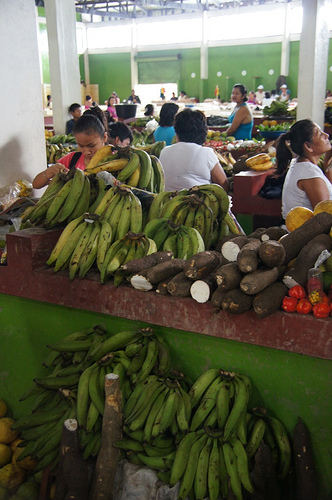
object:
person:
[219, 79, 255, 140]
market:
[0, 4, 332, 500]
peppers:
[279, 292, 300, 318]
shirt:
[276, 156, 332, 228]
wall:
[46, 35, 331, 108]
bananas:
[67, 215, 95, 283]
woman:
[30, 103, 129, 203]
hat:
[257, 83, 265, 91]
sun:
[40, 1, 332, 51]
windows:
[200, 0, 291, 51]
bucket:
[113, 102, 139, 123]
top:
[228, 102, 253, 138]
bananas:
[52, 162, 86, 227]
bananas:
[177, 220, 207, 261]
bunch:
[24, 162, 94, 223]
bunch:
[84, 139, 167, 196]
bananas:
[220, 367, 252, 445]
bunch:
[141, 215, 208, 262]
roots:
[218, 238, 242, 263]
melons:
[0, 411, 22, 447]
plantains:
[228, 431, 254, 494]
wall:
[0, 214, 332, 500]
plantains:
[222, 372, 251, 445]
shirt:
[155, 137, 221, 196]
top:
[153, 122, 179, 145]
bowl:
[185, 101, 196, 109]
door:
[130, 55, 180, 112]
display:
[7, 139, 239, 284]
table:
[0, 202, 332, 358]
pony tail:
[82, 104, 110, 133]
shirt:
[60, 148, 104, 180]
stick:
[88, 365, 129, 498]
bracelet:
[43, 169, 50, 183]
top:
[277, 159, 332, 229]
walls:
[0, 0, 51, 212]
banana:
[192, 178, 232, 219]